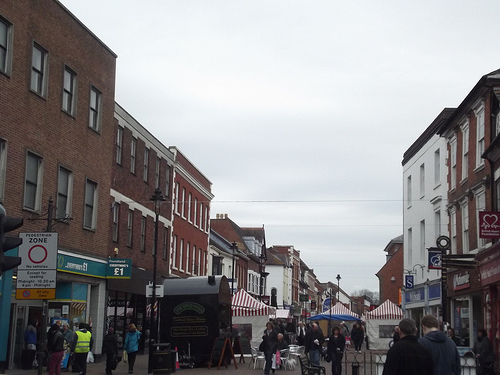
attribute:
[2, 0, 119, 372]
building — brick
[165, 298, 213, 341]
sign — black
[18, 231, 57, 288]
sign — white, pedestrian zone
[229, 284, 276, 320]
tent — red, white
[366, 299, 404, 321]
tent — red, white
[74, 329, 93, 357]
vest — yellow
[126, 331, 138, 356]
jacket — blue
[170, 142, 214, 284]
building — red brick, three-story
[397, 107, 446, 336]
building — white, three-story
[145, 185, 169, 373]
street light — black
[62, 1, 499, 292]
sky — grey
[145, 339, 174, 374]
trash can — black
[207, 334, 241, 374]
sign — standing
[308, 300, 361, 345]
tent — red, white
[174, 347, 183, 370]
safety cone — orange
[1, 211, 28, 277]
traffic light — black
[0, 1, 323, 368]
buildings — brick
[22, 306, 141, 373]
people — walking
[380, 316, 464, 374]
men — walking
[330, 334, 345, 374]
suit — black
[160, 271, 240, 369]
cabin — black